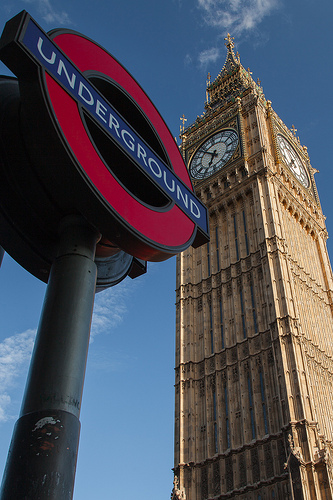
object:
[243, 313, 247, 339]
window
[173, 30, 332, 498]
building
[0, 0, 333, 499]
sky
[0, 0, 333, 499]
clouds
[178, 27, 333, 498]
wall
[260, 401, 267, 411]
window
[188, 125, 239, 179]
clock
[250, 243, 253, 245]
window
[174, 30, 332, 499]
tower